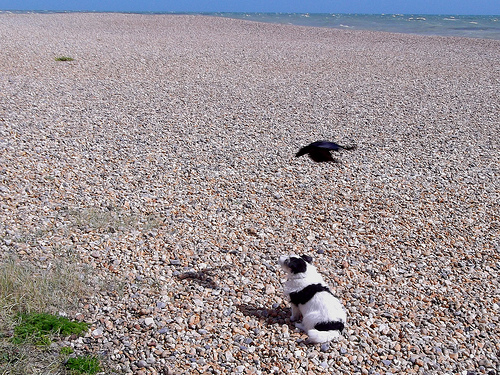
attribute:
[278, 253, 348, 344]
dog — black, white, small, sitting, fluffy, looking up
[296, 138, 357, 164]
bird — flying, black, flapping, in flight, crow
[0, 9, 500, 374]
beach — pebble-covered, brown, tan, rocky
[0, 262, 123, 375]
weeds — green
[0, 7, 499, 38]
ocean — in the distance, light blue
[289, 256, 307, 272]
ear — black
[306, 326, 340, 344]
tail — white, fluffy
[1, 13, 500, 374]
gravel — pink, gray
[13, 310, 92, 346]
grass — green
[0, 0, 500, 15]
sky — blue, clear, cloudless